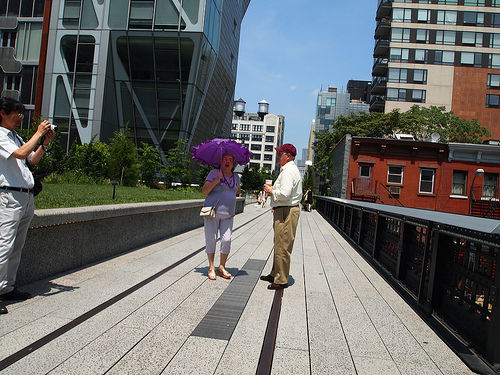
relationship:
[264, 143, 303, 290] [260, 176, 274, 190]
man holding coffee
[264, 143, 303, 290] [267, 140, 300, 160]
man has hat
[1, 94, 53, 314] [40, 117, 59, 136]
man taking picture with camera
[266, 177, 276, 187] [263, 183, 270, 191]
coffee cup in hand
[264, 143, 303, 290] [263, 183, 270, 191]
man has hand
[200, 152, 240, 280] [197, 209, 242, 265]
lady has pants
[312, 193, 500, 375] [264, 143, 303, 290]
rail next to man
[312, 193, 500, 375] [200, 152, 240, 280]
rail next to lady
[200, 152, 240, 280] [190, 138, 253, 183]
lady holding parasol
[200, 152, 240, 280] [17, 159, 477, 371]
lady on walkway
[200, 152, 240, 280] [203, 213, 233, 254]
lady has pants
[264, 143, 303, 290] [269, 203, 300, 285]
man on pants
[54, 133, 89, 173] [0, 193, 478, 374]
bush on sidewalk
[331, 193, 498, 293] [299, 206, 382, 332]
rail on walkway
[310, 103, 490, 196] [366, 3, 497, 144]
trees on building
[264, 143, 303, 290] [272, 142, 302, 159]
man on cap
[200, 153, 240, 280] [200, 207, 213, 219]
lady on purse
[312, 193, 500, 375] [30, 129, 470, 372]
rail along sidewalk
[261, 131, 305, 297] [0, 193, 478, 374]
man standing on sidewalk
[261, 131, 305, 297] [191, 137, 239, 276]
man standing next to woman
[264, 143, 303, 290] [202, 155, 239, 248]
man standing with woman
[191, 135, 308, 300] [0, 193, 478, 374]
couple standing on sidewalk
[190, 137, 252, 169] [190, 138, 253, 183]
edges on parasol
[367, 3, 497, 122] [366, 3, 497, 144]
windows on building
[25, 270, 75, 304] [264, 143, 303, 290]
shadow of a man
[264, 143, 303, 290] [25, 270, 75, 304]
man with a shadow